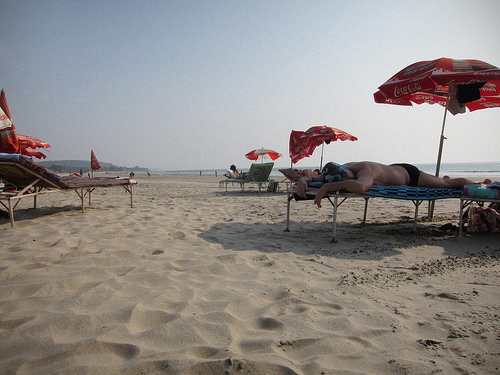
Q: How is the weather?
A: Sunny and hot.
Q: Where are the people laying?
A: On the beach.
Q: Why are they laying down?
A: They are relaxing.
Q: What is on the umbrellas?
A: Coca Cola logo.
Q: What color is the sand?
A: Tan.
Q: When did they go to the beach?
A: During the day.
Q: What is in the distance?
A: A mountain.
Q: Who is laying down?
A: People at the beach.